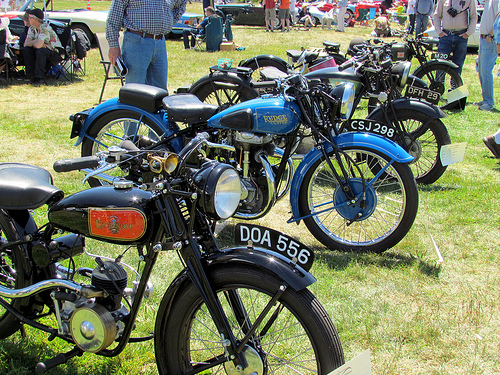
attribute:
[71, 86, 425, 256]
motorcycle — is blue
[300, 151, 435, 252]
wheel — on a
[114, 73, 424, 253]
motorcycle — has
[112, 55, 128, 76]
magazine — rolled up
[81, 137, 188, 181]
horn — small, bronze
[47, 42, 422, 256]
motorcycle — blue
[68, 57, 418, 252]
motorcycle — blue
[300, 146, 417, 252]
tire — skinny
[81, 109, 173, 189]
tire — tires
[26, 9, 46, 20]
cap — black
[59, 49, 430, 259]
bike — color blue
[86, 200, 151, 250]
logo — Rudge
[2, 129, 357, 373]
motorcycle — blue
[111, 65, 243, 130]
seat — black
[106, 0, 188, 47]
shirt — plaid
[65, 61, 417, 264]
bike — parked, is blue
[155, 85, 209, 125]
seat — is blue